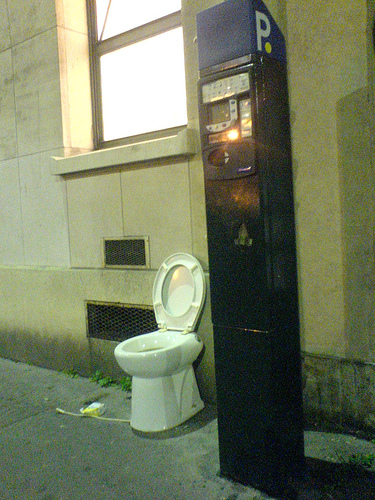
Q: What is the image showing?
A: It is showing a sidewalk.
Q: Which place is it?
A: It is a sidewalk.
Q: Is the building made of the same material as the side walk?
A: Yes, both the building and the side walk are made of concrete.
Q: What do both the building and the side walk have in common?
A: The material, both the building and the side walk are concrete.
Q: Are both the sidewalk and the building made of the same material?
A: Yes, both the sidewalk and the building are made of concrete.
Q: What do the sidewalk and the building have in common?
A: The material, both the sidewalk and the building are concrete.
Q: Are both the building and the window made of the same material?
A: No, the building is made of concrete and the window is made of metal.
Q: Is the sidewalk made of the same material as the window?
A: No, the sidewalk is made of cement and the window is made of metal.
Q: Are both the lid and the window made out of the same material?
A: No, the lid is made of plastic and the window is made of metal.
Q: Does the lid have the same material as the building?
A: No, the lid is made of plastic and the building is made of concrete.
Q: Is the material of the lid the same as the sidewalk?
A: No, the lid is made of plastic and the sidewalk is made of concrete.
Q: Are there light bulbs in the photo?
A: No, there are no light bulbs.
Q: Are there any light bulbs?
A: No, there are no light bulbs.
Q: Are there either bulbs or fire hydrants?
A: No, there are no bulbs or fire hydrants.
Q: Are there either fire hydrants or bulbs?
A: No, there are no bulbs or fire hydrants.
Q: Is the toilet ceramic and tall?
A: Yes, the toilet is ceramic and tall.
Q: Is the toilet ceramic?
A: Yes, the toilet is ceramic.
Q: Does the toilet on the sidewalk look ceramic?
A: Yes, the toilet is ceramic.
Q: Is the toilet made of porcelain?
A: Yes, the toilet is made of porcelain.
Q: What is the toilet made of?
A: The toilet is made of porcelain.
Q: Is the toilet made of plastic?
A: No, the toilet is made of porcelain.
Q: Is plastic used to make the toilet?
A: No, the toilet is made of porcelain.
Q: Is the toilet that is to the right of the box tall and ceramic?
A: Yes, the toilet is tall and ceramic.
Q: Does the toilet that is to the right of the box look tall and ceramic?
A: Yes, the toilet is tall and ceramic.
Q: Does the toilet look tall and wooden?
A: No, the toilet is tall but ceramic.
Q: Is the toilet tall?
A: Yes, the toilet is tall.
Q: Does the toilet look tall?
A: Yes, the toilet is tall.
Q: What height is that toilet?
A: The toilet is tall.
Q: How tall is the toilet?
A: The toilet is tall.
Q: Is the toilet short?
A: No, the toilet is tall.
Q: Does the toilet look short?
A: No, the toilet is tall.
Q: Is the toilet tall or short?
A: The toilet is tall.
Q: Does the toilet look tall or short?
A: The toilet is tall.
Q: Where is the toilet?
A: The toilet is on the sidewalk.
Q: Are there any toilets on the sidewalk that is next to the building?
A: Yes, there is a toilet on the sidewalk.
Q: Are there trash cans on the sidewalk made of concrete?
A: No, there is a toilet on the sidewalk.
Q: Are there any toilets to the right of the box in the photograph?
A: Yes, there is a toilet to the right of the box.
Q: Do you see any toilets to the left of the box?
A: No, the toilet is to the right of the box.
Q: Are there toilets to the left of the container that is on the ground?
A: No, the toilet is to the right of the box.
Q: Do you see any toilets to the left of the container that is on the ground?
A: No, the toilet is to the right of the box.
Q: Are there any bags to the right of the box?
A: No, there is a toilet to the right of the box.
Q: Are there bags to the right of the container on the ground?
A: No, there is a toilet to the right of the box.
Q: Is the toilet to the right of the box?
A: Yes, the toilet is to the right of the box.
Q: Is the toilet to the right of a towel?
A: No, the toilet is to the right of the box.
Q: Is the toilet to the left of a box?
A: No, the toilet is to the right of a box.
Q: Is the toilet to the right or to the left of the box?
A: The toilet is to the right of the box.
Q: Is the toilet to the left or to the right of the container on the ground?
A: The toilet is to the right of the box.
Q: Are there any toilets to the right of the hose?
A: Yes, there is a toilet to the right of the hose.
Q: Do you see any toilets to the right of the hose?
A: Yes, there is a toilet to the right of the hose.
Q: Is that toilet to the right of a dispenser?
A: No, the toilet is to the right of the water hose.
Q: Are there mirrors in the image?
A: No, there are no mirrors.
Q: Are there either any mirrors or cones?
A: No, there are no mirrors or cones.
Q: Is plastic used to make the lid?
A: Yes, the lid is made of plastic.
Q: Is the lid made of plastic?
A: Yes, the lid is made of plastic.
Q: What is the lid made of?
A: The lid is made of plastic.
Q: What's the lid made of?
A: The lid is made of plastic.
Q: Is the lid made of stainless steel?
A: No, the lid is made of plastic.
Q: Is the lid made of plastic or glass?
A: The lid is made of plastic.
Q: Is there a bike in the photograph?
A: No, there are no bikes.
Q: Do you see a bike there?
A: No, there are no bikes.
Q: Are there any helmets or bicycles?
A: No, there are no bicycles or helmets.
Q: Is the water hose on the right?
A: No, the water hose is on the left of the image.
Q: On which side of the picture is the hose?
A: The hose is on the left of the image.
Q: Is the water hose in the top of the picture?
A: No, the water hose is in the bottom of the image.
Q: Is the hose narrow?
A: Yes, the hose is narrow.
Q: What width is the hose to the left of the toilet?
A: The water hose is narrow.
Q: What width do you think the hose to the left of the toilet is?
A: The water hose is narrow.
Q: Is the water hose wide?
A: No, the water hose is narrow.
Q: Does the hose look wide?
A: No, the hose is narrow.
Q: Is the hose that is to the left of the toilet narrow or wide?
A: The water hose is narrow.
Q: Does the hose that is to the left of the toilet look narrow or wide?
A: The water hose is narrow.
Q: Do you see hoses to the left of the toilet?
A: Yes, there is a hose to the left of the toilet.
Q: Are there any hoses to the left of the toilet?
A: Yes, there is a hose to the left of the toilet.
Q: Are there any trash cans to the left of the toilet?
A: No, there is a hose to the left of the toilet.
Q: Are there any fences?
A: No, there are no fences.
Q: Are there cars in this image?
A: No, there are no cars.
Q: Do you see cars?
A: No, there are no cars.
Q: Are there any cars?
A: No, there are no cars.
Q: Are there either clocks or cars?
A: No, there are no cars or clocks.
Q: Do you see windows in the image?
A: Yes, there is a window.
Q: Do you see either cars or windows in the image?
A: Yes, there is a window.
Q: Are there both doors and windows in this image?
A: No, there is a window but no doors.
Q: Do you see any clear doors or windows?
A: Yes, there is a clear window.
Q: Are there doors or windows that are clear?
A: Yes, the window is clear.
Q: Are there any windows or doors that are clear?
A: Yes, the window is clear.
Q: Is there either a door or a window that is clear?
A: Yes, the window is clear.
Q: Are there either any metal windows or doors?
A: Yes, there is a metal window.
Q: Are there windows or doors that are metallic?
A: Yes, the window is metallic.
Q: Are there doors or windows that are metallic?
A: Yes, the window is metallic.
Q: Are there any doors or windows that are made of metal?
A: Yes, the window is made of metal.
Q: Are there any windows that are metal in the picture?
A: Yes, there is a metal window.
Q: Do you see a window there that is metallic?
A: Yes, there is a window that is metallic.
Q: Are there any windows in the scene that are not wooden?
A: Yes, there is a metallic window.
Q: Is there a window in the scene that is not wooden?
A: Yes, there is a metallic window.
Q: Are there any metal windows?
A: Yes, there is a window that is made of metal.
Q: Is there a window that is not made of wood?
A: Yes, there is a window that is made of metal.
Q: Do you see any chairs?
A: No, there are no chairs.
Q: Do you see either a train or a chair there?
A: No, there are no chairs or trains.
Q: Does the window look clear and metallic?
A: Yes, the window is clear and metallic.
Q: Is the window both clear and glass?
A: No, the window is clear but metallic.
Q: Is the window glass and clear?
A: No, the window is clear but metallic.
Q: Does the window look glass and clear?
A: No, the window is clear but metallic.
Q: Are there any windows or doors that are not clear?
A: No, there is a window but it is clear.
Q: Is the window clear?
A: Yes, the window is clear.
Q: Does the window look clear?
A: Yes, the window is clear.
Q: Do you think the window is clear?
A: Yes, the window is clear.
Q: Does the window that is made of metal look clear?
A: Yes, the window is clear.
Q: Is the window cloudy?
A: No, the window is clear.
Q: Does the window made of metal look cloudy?
A: No, the window is clear.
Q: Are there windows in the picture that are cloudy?
A: No, there is a window but it is clear.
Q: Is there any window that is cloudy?
A: No, there is a window but it is clear.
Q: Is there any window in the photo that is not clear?
A: No, there is a window but it is clear.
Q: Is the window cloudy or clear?
A: The window is clear.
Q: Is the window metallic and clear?
A: Yes, the window is metallic and clear.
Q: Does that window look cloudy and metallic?
A: No, the window is metallic but clear.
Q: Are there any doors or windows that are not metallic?
A: No, there is a window but it is metallic.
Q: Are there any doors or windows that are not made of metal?
A: No, there is a window but it is made of metal.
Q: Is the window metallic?
A: Yes, the window is metallic.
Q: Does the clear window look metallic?
A: Yes, the window is metallic.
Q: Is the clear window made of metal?
A: Yes, the window is made of metal.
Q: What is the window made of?
A: The window is made of metal.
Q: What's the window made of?
A: The window is made of metal.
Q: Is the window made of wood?
A: No, the window is made of metal.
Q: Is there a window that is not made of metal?
A: No, there is a window but it is made of metal.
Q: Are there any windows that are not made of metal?
A: No, there is a window but it is made of metal.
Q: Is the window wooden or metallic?
A: The window is metallic.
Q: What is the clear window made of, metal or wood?
A: The window is made of metal.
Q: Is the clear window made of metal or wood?
A: The window is made of metal.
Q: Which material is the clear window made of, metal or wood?
A: The window is made of metal.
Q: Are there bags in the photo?
A: No, there are no bags.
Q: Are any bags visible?
A: No, there are no bags.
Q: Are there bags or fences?
A: No, there are no bags or fences.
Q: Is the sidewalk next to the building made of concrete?
A: Yes, the side walk is made of concrete.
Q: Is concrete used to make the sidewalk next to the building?
A: Yes, the side walk is made of concrete.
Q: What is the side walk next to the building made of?
A: The sidewalk is made of concrete.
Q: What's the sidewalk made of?
A: The sidewalk is made of concrete.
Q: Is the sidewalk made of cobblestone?
A: No, the sidewalk is made of concrete.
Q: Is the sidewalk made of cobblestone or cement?
A: The sidewalk is made of cement.